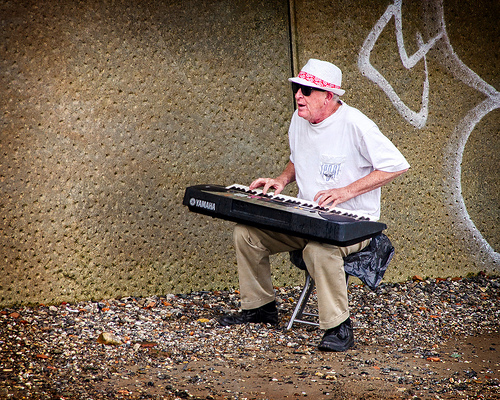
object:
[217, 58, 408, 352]
man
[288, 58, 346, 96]
hat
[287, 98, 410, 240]
shirt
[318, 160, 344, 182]
design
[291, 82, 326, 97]
sunglasses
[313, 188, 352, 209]
left hand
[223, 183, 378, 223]
keyboard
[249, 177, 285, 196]
right hand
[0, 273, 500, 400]
ground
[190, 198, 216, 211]
lettering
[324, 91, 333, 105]
ear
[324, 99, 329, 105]
hearing aid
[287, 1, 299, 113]
dent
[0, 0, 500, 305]
wall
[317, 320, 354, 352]
shoe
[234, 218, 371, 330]
pants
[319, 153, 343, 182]
pocket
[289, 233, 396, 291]
bag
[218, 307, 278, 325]
foot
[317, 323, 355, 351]
foot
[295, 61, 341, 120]
head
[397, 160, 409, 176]
elbow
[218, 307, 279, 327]
shoe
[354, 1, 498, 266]
tag